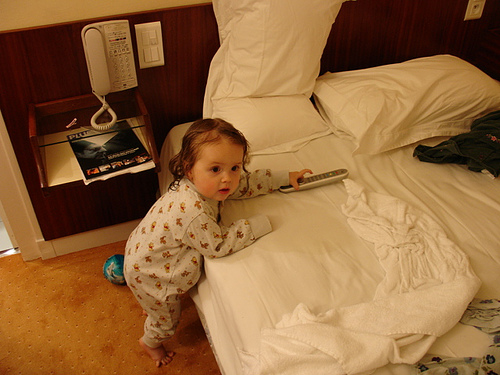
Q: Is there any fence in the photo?
A: No, there are no fences.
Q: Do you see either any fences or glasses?
A: No, there are no fences or glasses.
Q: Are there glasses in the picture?
A: No, there are no glasses.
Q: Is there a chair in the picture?
A: No, there are no chairs.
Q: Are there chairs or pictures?
A: No, there are no chairs or pictures.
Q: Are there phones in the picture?
A: Yes, there is a phone.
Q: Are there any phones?
A: Yes, there is a phone.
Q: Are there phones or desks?
A: Yes, there is a phone.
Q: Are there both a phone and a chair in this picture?
A: No, there is a phone but no chairs.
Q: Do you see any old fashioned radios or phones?
A: Yes, there is an old fashioned phone.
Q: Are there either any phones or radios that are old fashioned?
A: Yes, the phone is old fashioned.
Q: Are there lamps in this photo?
A: No, there are no lamps.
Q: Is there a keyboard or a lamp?
A: No, there are no lamps or keyboards.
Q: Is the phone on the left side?
A: Yes, the phone is on the left of the image.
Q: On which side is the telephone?
A: The telephone is on the left of the image.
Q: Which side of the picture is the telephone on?
A: The telephone is on the left of the image.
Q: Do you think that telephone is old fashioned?
A: Yes, the telephone is old fashioned.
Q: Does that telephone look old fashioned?
A: Yes, the telephone is old fashioned.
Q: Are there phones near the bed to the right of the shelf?
A: Yes, there is a phone near the bed.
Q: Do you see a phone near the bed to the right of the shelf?
A: Yes, there is a phone near the bed.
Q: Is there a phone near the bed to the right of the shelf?
A: Yes, there is a phone near the bed.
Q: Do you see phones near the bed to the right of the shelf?
A: Yes, there is a phone near the bed.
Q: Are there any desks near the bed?
A: No, there is a phone near the bed.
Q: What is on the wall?
A: The phone is on the wall.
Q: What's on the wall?
A: The phone is on the wall.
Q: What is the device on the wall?
A: The device is a phone.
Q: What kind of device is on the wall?
A: The device is a phone.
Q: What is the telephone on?
A: The telephone is on the wall.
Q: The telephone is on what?
A: The telephone is on the wall.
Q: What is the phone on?
A: The telephone is on the wall.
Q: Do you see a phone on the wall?
A: Yes, there is a phone on the wall.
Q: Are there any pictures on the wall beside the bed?
A: No, there is a phone on the wall.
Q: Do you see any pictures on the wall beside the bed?
A: No, there is a phone on the wall.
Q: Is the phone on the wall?
A: Yes, the phone is on the wall.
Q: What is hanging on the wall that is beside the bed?
A: The telephone is hanging on the wall.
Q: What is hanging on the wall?
A: The telephone is hanging on the wall.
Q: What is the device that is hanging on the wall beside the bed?
A: The device is a phone.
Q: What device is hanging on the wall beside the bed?
A: The device is a phone.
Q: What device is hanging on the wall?
A: The device is a phone.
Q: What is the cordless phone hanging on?
A: The telephone is hanging on the wall.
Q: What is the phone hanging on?
A: The telephone is hanging on the wall.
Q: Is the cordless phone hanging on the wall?
A: Yes, the phone is hanging on the wall.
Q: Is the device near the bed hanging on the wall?
A: Yes, the phone is hanging on the wall.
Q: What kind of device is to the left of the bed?
A: The device is a phone.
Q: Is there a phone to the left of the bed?
A: Yes, there is a phone to the left of the bed.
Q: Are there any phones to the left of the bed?
A: Yes, there is a phone to the left of the bed.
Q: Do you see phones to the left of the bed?
A: Yes, there is a phone to the left of the bed.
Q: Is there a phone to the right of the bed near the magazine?
A: No, the phone is to the left of the bed.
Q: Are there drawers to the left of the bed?
A: No, there is a phone to the left of the bed.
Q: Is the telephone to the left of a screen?
A: No, the telephone is to the left of the bed.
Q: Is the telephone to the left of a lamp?
A: No, the telephone is to the left of a pillow.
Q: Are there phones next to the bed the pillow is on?
A: Yes, there is a phone next to the bed.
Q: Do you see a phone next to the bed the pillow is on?
A: Yes, there is a phone next to the bed.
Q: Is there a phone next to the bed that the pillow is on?
A: Yes, there is a phone next to the bed.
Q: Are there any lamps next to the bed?
A: No, there is a phone next to the bed.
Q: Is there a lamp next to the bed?
A: No, there is a phone next to the bed.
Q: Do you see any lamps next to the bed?
A: No, there is a phone next to the bed.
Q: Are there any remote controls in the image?
A: Yes, there is a remote control.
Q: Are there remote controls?
A: Yes, there is a remote control.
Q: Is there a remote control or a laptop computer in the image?
A: Yes, there is a remote control.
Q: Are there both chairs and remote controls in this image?
A: No, there is a remote control but no chairs.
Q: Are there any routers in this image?
A: No, there are no routers.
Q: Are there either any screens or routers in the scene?
A: No, there are no routers or screens.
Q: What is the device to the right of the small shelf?
A: The device is a remote control.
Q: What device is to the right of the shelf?
A: The device is a remote control.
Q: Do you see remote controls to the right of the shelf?
A: Yes, there is a remote control to the right of the shelf.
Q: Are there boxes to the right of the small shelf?
A: No, there is a remote control to the right of the shelf.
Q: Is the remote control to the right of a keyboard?
A: No, the remote control is to the right of the shelf.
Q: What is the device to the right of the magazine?
A: The device is a remote control.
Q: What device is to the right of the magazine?
A: The device is a remote control.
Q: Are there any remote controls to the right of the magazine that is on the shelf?
A: Yes, there is a remote control to the right of the magazine.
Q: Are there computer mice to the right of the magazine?
A: No, there is a remote control to the right of the magazine.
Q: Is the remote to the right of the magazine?
A: Yes, the remote is to the right of the magazine.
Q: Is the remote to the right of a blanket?
A: No, the remote is to the right of the magazine.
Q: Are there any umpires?
A: No, there are no umpires.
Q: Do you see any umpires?
A: No, there are no umpires.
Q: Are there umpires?
A: No, there are no umpires.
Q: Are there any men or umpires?
A: No, there are no umpires or men.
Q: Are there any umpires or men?
A: No, there are no umpires or men.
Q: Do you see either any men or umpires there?
A: No, there are no umpires or men.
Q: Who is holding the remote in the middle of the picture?
A: The girl is holding the remote.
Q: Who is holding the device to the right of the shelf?
A: The girl is holding the remote.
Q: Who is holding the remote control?
A: The girl is holding the remote.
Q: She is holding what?
A: The girl is holding the remote control.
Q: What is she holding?
A: The girl is holding the remote control.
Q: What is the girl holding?
A: The girl is holding the remote control.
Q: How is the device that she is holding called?
A: The device is a remote control.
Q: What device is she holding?
A: The girl is holding the remote.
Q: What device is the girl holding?
A: The girl is holding the remote.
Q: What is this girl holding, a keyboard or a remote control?
A: The girl is holding a remote control.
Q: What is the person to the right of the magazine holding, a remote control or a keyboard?
A: The girl is holding a remote control.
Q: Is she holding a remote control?
A: Yes, the girl is holding a remote control.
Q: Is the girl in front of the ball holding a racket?
A: No, the girl is holding a remote control.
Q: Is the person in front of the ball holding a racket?
A: No, the girl is holding a remote control.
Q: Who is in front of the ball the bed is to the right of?
A: The girl is in front of the ball.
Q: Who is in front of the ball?
A: The girl is in front of the ball.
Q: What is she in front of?
A: The girl is in front of the ball.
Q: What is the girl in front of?
A: The girl is in front of the ball.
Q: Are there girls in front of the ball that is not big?
A: Yes, there is a girl in front of the ball.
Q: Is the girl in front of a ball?
A: Yes, the girl is in front of a ball.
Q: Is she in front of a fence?
A: No, the girl is in front of a ball.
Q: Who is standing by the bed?
A: The girl is standing by the bed.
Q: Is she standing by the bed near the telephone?
A: Yes, the girl is standing by the bed.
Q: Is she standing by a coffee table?
A: No, the girl is standing by the bed.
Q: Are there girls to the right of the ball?
A: Yes, there is a girl to the right of the ball.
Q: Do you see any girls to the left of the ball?
A: No, the girl is to the right of the ball.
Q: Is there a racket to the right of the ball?
A: No, there is a girl to the right of the ball.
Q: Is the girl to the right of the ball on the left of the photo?
A: Yes, the girl is to the right of the ball.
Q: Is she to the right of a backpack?
A: No, the girl is to the right of the ball.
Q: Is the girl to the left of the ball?
A: No, the girl is to the right of the ball.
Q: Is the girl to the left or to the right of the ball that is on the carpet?
A: The girl is to the right of the ball.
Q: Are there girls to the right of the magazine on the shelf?
A: Yes, there is a girl to the right of the magazine.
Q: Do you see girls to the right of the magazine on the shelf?
A: Yes, there is a girl to the right of the magazine.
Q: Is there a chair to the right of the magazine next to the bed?
A: No, there is a girl to the right of the magazine.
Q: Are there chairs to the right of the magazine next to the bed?
A: No, there is a girl to the right of the magazine.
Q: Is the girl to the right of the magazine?
A: Yes, the girl is to the right of the magazine.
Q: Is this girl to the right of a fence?
A: No, the girl is to the right of the magazine.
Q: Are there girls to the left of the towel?
A: Yes, there is a girl to the left of the towel.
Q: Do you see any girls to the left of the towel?
A: Yes, there is a girl to the left of the towel.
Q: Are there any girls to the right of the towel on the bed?
A: No, the girl is to the left of the towel.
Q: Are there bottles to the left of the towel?
A: No, there is a girl to the left of the towel.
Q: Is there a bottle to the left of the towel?
A: No, there is a girl to the left of the towel.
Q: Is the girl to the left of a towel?
A: Yes, the girl is to the left of a towel.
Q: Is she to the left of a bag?
A: No, the girl is to the left of a towel.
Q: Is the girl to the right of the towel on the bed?
A: No, the girl is to the left of the towel.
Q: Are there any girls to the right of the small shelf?
A: Yes, there is a girl to the right of the shelf.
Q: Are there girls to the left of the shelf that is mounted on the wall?
A: No, the girl is to the right of the shelf.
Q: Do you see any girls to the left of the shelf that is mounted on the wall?
A: No, the girl is to the right of the shelf.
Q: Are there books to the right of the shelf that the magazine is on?
A: No, there is a girl to the right of the shelf.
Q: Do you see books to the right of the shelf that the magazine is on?
A: No, there is a girl to the right of the shelf.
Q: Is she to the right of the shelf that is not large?
A: Yes, the girl is to the right of the shelf.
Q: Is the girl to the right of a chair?
A: No, the girl is to the right of the shelf.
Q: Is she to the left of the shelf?
A: No, the girl is to the right of the shelf.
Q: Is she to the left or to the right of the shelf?
A: The girl is to the right of the shelf.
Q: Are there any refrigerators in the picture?
A: No, there are no refrigerators.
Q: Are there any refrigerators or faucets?
A: No, there are no refrigerators or faucets.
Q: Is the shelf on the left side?
A: Yes, the shelf is on the left of the image.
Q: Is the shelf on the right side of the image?
A: No, the shelf is on the left of the image.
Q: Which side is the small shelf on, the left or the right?
A: The shelf is on the left of the image.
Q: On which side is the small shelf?
A: The shelf is on the left of the image.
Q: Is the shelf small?
A: Yes, the shelf is small.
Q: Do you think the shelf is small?
A: Yes, the shelf is small.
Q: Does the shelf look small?
A: Yes, the shelf is small.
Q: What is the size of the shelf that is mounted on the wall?
A: The shelf is small.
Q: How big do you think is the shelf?
A: The shelf is small.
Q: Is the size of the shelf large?
A: No, the shelf is small.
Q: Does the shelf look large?
A: No, the shelf is small.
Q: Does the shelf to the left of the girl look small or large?
A: The shelf is small.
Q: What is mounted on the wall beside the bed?
A: The shelf is mounted on the wall.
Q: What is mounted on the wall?
A: The shelf is mounted on the wall.